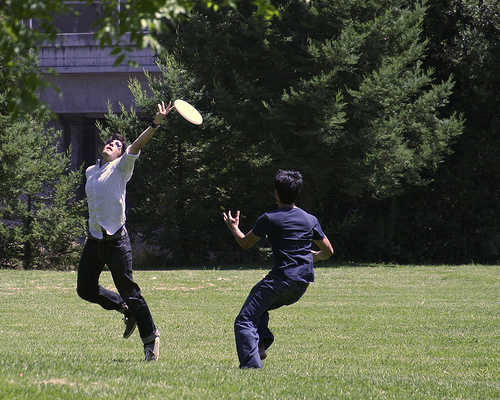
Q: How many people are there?
A: 2.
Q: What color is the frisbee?
A: White.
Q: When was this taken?
A: Daytime.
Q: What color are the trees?
A: Green.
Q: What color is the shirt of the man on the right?
A: Blue.